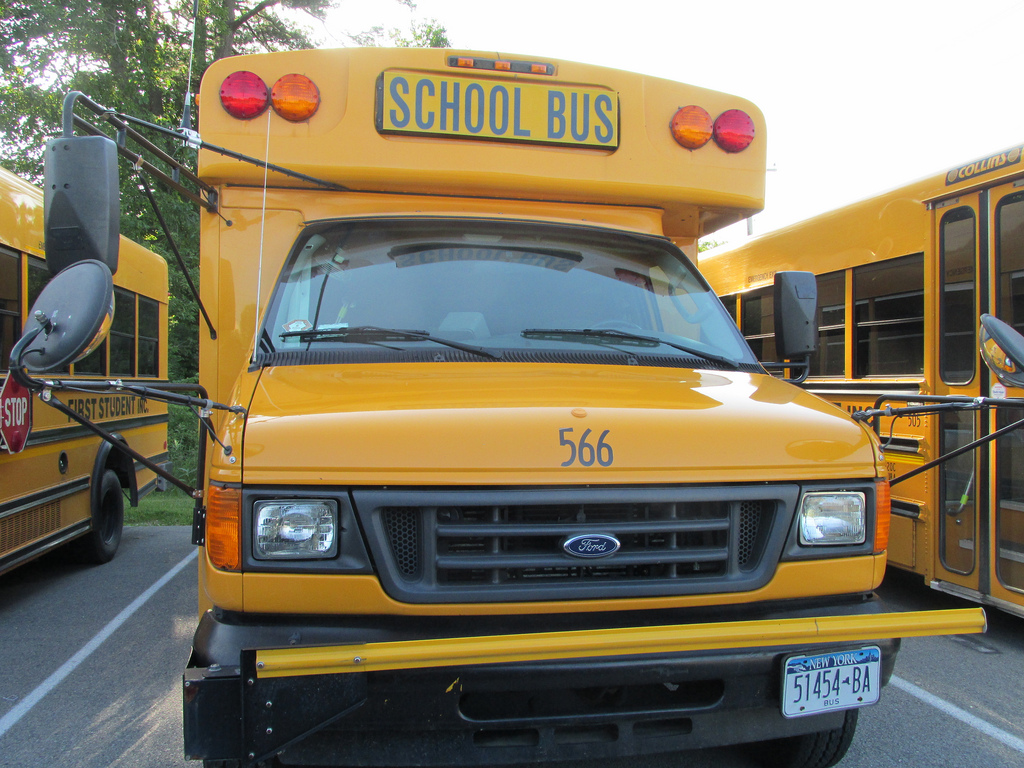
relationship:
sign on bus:
[373, 61, 624, 150] [170, 31, 1004, 758]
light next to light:
[710, 109, 756, 153] [671, 98, 713, 153]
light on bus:
[271, 70, 326, 127] [170, 31, 1004, 758]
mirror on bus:
[38, 124, 129, 278] [170, 31, 1004, 758]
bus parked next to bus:
[170, 31, 1004, 758] [688, 128, 1023, 634]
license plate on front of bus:
[781, 646, 880, 720] [170, 31, 1004, 758]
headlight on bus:
[249, 495, 343, 552] [170, 31, 1004, 758]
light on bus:
[204, 478, 244, 561] [170, 31, 1004, 758]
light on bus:
[872, 469, 892, 539] [170, 31, 1004, 758]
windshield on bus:
[264, 210, 749, 362] [170, 31, 1004, 758]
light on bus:
[714, 109, 757, 152] [170, 31, 1004, 758]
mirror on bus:
[770, 260, 829, 360] [170, 31, 1004, 758]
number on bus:
[547, 407, 638, 477] [6, 48, 987, 768]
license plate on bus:
[776, 640, 893, 720] [6, 48, 987, 768]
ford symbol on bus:
[550, 528, 628, 563] [170, 31, 1004, 758]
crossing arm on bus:
[238, 593, 1001, 695] [170, 31, 1004, 758]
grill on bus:
[347, 480, 795, 602] [6, 48, 987, 768]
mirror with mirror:
[44, 135, 120, 277] [5, 253, 120, 388]